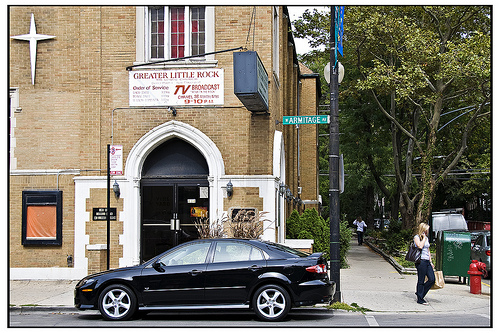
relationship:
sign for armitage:
[282, 116, 331, 125] [284, 116, 320, 126]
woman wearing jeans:
[409, 223, 435, 306] [414, 259, 435, 298]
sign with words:
[128, 68, 224, 109] [133, 70, 220, 104]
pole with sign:
[330, 4, 342, 308] [282, 116, 331, 125]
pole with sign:
[330, 4, 342, 308] [338, 151, 345, 193]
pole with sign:
[330, 4, 342, 308] [334, 4, 345, 58]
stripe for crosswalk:
[364, 313, 380, 326] [364, 313, 489, 329]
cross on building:
[11, 13, 56, 88] [10, 2, 319, 281]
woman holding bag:
[409, 223, 435, 306] [405, 246, 423, 261]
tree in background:
[297, 51, 369, 194] [289, 7, 491, 242]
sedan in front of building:
[74, 238, 337, 320] [10, 2, 319, 281]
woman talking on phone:
[409, 223, 435, 306] [420, 230, 426, 238]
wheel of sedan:
[97, 284, 136, 321] [74, 238, 337, 320]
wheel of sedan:
[250, 284, 291, 322] [74, 238, 337, 320]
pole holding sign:
[330, 4, 342, 308] [334, 4, 345, 58]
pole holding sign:
[330, 4, 342, 308] [338, 151, 345, 193]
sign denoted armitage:
[282, 116, 331, 125] [288, 116, 321, 123]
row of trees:
[341, 8, 489, 262] [340, 7, 492, 259]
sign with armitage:
[282, 116, 331, 125] [284, 116, 320, 126]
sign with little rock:
[128, 68, 224, 109] [170, 70, 220, 80]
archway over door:
[138, 134, 207, 178] [142, 183, 175, 264]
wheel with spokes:
[97, 284, 136, 321] [106, 291, 130, 314]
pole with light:
[330, 4, 342, 308] [322, 61, 343, 83]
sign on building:
[128, 68, 224, 109] [10, 2, 319, 281]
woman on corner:
[409, 223, 435, 306] [402, 272, 493, 328]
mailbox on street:
[440, 231, 471, 283] [464, 217, 490, 277]